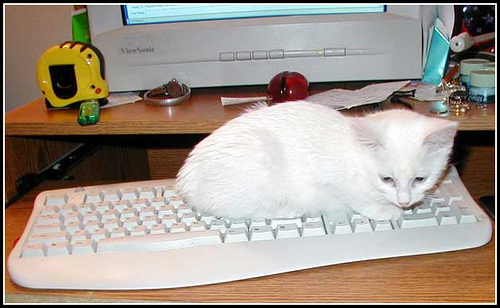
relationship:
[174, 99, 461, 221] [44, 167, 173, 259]
cat on top of keyboard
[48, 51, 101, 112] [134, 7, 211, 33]
toy next to computer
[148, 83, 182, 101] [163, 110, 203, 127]
object on top of desk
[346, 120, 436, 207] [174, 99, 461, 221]
head of cat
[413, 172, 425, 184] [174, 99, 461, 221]
eye of cat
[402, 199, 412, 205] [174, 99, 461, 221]
nose on cat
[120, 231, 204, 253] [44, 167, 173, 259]
space bar on top of keyboard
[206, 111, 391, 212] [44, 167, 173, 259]
kitten on top of keyboard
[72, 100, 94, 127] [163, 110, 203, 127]
watch on desk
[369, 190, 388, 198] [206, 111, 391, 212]
whiskers attached to kitten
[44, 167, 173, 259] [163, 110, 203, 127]
keyboard on top of desk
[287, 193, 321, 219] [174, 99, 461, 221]
stomach attached to cat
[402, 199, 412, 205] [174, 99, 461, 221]
nose of cat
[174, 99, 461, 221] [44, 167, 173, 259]
cat lying on keyboard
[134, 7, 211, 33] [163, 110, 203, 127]
computer on desk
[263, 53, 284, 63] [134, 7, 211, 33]
knobs are on computer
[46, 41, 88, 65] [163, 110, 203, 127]
pencil sharpener on desk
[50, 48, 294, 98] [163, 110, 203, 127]
paraphernalia on desk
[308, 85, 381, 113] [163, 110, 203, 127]
papers lying on desk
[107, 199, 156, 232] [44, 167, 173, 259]
keys on top of keyboard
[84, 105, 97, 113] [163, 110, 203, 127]
cigarette lighter on desk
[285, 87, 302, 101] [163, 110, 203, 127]
tape measure on desk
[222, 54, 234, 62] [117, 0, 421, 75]
buttons attached to monitor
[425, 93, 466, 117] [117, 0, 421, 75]
wristwatch in front of monitor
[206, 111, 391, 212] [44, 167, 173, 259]
kitten lying on keyboard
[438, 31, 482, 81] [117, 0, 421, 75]
jars are next to monitor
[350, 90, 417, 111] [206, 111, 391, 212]
jewelery behind kitten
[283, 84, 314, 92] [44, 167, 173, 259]
mouse in front of keyboard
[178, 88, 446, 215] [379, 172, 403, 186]
cat has eye